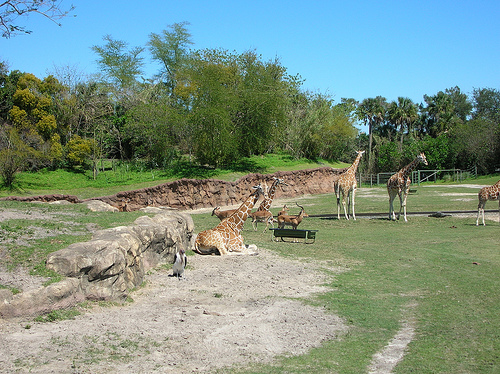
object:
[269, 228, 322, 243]
bench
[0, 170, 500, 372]
ground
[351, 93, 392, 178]
trees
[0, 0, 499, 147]
sky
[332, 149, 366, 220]
giraffes